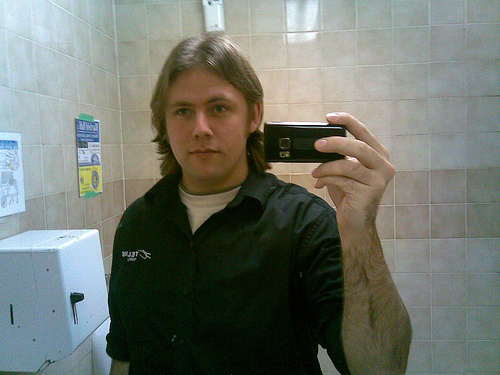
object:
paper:
[75, 115, 105, 197]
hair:
[351, 247, 388, 327]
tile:
[465, 168, 499, 203]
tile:
[468, 130, 500, 167]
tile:
[393, 135, 429, 171]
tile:
[429, 236, 466, 275]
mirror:
[0, 0, 499, 373]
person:
[95, 19, 416, 373]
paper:
[0, 132, 27, 222]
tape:
[79, 112, 92, 121]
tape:
[83, 190, 99, 197]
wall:
[119, 1, 499, 371]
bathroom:
[0, 0, 498, 372]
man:
[92, 32, 415, 373]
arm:
[330, 202, 411, 374]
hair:
[350, 255, 380, 344]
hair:
[148, 35, 277, 176]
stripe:
[396, 140, 489, 287]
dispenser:
[0, 228, 107, 364]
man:
[107, 23, 417, 374]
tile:
[427, 57, 468, 99]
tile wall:
[350, 0, 497, 130]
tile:
[430, 169, 466, 202]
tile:
[430, 24, 465, 62]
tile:
[430, 97, 465, 131]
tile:
[430, 130, 467, 170]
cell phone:
[261, 119, 348, 162]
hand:
[309, 112, 395, 221]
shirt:
[105, 179, 361, 374]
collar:
[227, 169, 277, 214]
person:
[102, 35, 412, 372]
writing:
[119, 248, 153, 262]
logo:
[122, 247, 153, 263]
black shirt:
[116, 164, 346, 373]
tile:
[430, 202, 467, 239]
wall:
[0, 2, 497, 373]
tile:
[430, 307, 467, 341]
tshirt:
[105, 178, 340, 373]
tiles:
[397, 144, 475, 236]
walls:
[296, 28, 462, 117]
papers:
[0, 115, 105, 217]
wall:
[1, 0, 125, 373]